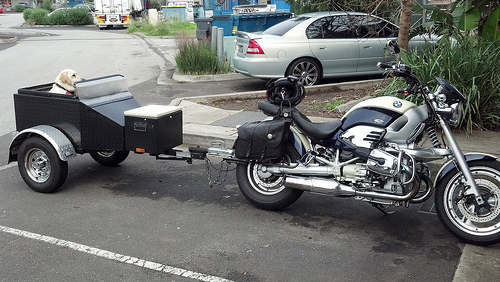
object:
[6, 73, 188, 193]
cart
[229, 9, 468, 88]
car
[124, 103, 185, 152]
cooler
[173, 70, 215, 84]
patch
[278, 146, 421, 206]
silver engine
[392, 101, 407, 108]
emblem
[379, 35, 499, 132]
grass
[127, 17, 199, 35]
grass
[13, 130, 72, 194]
wheel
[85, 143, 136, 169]
wheel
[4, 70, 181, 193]
trailer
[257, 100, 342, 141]
black seat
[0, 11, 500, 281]
ground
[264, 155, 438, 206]
exhaust pipes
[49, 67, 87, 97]
dog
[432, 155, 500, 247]
wheel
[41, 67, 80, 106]
lab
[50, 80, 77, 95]
collar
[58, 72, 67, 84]
brown ear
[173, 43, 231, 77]
grass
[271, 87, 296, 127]
helmet seat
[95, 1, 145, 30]
trailer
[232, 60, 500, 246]
motorcycle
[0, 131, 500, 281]
sidewalk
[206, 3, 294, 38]
dumpster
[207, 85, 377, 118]
dirt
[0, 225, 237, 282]
line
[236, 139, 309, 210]
wheel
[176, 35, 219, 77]
bush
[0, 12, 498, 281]
road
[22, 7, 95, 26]
grass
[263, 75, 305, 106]
helmet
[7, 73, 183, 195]
attachment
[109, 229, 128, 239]
patch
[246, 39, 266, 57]
headlights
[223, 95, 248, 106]
dirt patch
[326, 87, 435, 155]
tank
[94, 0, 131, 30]
back end